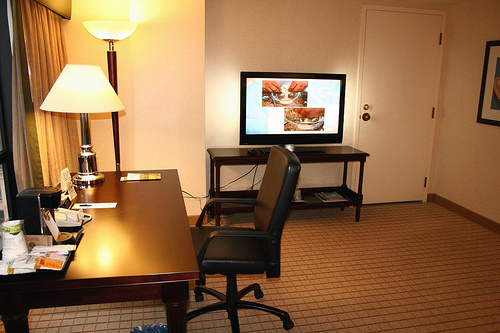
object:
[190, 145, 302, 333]
office chair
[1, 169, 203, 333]
table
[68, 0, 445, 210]
wall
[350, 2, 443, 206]
door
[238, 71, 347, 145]
tv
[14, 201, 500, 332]
floor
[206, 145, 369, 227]
table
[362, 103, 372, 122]
lock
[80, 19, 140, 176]
lamps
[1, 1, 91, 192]
curtains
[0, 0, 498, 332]
room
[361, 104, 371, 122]
knob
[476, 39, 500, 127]
picture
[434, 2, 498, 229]
wall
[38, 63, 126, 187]
lamp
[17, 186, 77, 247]
coffee maker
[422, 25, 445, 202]
hinges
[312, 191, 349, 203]
magazine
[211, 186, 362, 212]
shelf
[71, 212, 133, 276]
light reflection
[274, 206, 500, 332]
squares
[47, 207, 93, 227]
telephone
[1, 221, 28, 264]
cups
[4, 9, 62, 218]
window